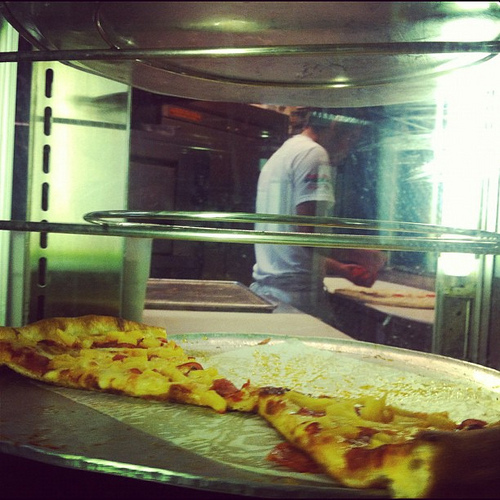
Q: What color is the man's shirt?
A: White.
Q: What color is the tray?
A: SIlver.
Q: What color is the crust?
A: Brown.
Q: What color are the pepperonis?
A: Red.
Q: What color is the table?
A: White.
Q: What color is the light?
A: Bright.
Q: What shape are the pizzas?
A: Triangular.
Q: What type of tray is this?
A: A pizza pan.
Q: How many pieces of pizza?
A: 2.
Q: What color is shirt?
A: White.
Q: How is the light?
A: Bright.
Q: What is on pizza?
A: Toppings.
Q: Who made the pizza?
A: The man.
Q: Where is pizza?
A: On metal plate.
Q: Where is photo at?
A: Pizzeria.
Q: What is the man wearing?
A: T-shirt.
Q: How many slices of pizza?
A: 2.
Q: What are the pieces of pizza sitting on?
A: An aluminum pan.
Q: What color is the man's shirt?
A: White.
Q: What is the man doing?
A: Making pizza.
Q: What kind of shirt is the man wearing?
A: A t-shirt.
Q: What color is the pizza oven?
A: Black.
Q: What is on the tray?
A: Pizza.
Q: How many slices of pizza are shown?
A: Two.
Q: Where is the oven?
A: On the left.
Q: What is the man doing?
A: Making pizza.